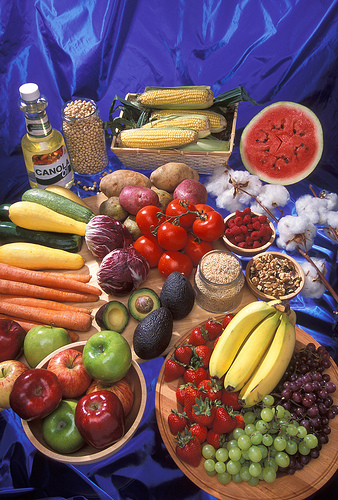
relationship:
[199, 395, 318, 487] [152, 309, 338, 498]
grapes on tray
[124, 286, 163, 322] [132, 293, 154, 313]
avocado with seed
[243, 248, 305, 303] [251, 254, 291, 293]
bowl with walnuts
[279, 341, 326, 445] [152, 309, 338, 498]
grapes on tray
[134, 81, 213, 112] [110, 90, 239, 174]
corn in basket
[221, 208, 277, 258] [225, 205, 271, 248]
bowl of raspberries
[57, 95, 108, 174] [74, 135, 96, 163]
jar full of nuts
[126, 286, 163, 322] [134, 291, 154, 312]
avocado has pit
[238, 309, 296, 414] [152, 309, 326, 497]
banana lying on top of tray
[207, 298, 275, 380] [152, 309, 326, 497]
banana lying on top of tray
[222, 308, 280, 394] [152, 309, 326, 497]
banana lying on top of tray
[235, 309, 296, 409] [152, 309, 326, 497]
banana lying on top of tray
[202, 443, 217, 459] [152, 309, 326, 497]
grape lying on top of tray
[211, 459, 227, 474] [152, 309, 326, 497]
grape lying on top of tray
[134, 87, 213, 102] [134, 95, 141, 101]
corn attached to cob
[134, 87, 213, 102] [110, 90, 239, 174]
corn lying inside basket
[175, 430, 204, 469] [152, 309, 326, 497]
strawberries lying on top of tray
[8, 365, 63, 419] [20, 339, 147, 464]
apple lying inside bowl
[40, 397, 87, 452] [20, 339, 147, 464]
apple lying inside bowl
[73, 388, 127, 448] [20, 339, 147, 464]
apple lying inside bowl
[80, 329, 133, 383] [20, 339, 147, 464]
apple lying inside bowl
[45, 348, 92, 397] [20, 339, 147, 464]
apple lying inside bowl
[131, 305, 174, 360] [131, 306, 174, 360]
skin covering avocado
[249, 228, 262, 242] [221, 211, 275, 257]
raspberries lying inside bowl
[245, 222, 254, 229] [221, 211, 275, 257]
raspberry lying inside bowl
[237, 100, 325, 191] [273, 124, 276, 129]
watermelon has seed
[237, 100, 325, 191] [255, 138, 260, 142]
watermelon has seed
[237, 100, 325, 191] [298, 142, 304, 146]
watermelon has seed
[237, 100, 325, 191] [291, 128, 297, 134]
watermelon has seed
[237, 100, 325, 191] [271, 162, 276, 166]
watermelon has seed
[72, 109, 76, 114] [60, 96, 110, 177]
bean sitting inside jar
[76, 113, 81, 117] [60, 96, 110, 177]
bean sitting inside jar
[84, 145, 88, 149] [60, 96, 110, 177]
bean sitting inside jar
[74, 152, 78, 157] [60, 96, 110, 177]
bean sitting inside jar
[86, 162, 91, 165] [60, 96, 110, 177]
bean sitting inside jar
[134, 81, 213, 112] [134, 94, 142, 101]
corn attached to cob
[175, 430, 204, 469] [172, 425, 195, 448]
strawberries attached to stem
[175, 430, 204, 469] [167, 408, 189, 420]
strawberries attached to stem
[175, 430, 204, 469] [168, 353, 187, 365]
strawberries attached to stem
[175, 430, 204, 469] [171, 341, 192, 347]
strawberries attached to stem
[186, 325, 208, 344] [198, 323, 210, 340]
strawberry attached to stem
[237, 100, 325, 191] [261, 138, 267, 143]
watermelon has seed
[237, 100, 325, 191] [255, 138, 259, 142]
watermelon has seed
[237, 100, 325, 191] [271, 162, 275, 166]
watermelon has seed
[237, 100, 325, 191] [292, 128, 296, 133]
watermelon has seed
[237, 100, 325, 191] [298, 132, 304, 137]
watermelon has seed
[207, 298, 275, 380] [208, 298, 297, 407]
banana attached to bunch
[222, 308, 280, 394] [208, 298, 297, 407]
banana attached to bunch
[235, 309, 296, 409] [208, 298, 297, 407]
banana attached to bunch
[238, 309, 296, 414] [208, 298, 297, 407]
banana attached to bunch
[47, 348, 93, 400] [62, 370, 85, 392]
apple has a hint of a strip in skin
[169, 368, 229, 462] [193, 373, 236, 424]
strawberries with caps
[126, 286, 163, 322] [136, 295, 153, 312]
avocado with pit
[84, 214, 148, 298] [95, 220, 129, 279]
radicchio has leaves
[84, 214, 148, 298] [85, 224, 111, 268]
radicchio with veins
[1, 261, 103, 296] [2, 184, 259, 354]
vegetable on tray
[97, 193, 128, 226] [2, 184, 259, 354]
vegetable on tray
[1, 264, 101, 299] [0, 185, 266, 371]
vegetable on tray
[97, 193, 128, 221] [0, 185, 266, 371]
vegetable on tray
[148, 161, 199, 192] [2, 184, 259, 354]
vegetable on tray